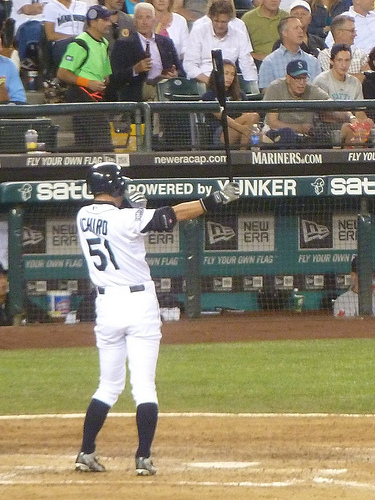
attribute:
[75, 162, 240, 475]
player — baseball, swinging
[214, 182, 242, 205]
glove — gray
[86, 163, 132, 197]
helmet — navy, black, dark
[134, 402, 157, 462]
sock — navy, long, blue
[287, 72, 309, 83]
glasses — pair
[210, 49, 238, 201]
bat — black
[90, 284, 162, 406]
pants — white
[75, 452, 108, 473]
shoe — gray, white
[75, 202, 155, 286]
shirt — white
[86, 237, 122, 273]
number — printed, black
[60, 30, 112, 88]
shirt — green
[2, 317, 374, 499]
field — baseball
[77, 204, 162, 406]
dress — white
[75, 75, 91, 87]
armband — orange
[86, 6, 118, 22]
cap — blue